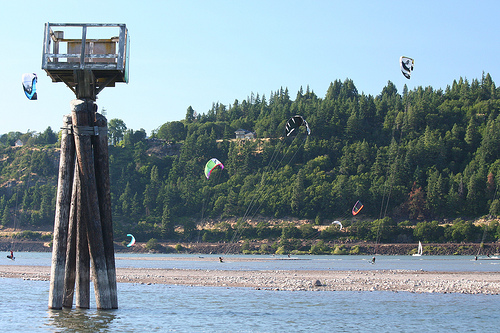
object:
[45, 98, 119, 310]
posts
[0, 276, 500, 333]
water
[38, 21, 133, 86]
platform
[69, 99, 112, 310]
log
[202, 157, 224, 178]
kite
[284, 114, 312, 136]
kite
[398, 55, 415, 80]
kite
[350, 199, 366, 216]
kite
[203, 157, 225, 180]
parasail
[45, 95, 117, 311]
poles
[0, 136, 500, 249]
ground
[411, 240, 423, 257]
windsurfer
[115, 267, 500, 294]
rocky sandbar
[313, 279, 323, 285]
rock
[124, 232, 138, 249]
parasail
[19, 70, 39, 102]
kite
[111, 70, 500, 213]
green trees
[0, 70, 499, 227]
hill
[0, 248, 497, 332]
water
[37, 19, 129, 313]
tower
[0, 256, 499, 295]
beach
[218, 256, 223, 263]
person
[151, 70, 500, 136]
built upon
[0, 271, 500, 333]
water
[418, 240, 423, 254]
sail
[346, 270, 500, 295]
sand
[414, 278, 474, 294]
rocks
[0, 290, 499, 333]
water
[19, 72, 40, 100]
parasail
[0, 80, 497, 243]
hill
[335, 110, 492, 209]
trees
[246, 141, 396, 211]
trees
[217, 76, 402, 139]
trees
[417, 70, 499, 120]
trees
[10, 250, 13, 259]
person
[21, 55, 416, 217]
kites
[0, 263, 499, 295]
beach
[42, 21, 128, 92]
stand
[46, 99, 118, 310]
brace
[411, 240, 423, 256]
boat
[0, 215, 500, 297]
ground